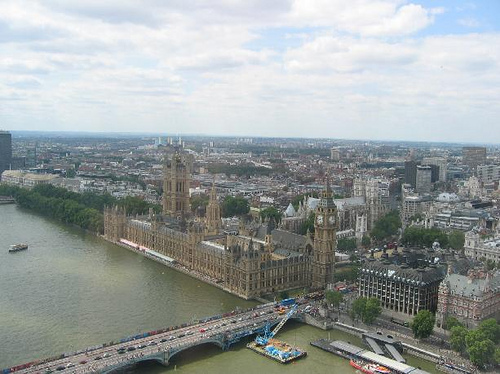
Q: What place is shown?
A: It is a city.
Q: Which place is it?
A: It is a city.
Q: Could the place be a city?
A: Yes, it is a city.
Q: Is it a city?
A: Yes, it is a city.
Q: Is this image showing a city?
A: Yes, it is showing a city.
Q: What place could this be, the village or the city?
A: It is the city.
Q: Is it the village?
A: No, it is the city.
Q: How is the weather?
A: It is cloudy.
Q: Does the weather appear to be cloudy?
A: Yes, it is cloudy.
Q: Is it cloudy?
A: Yes, it is cloudy.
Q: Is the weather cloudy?
A: Yes, it is cloudy.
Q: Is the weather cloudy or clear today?
A: It is cloudy.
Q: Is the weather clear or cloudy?
A: It is cloudy.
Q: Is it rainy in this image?
A: No, it is cloudy.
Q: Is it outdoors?
A: Yes, it is outdoors.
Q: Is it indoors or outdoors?
A: It is outdoors.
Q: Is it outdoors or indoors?
A: It is outdoors.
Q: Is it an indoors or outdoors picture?
A: It is outdoors.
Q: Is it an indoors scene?
A: No, it is outdoors.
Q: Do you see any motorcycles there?
A: No, there are no motorcycles.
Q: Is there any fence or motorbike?
A: No, there are no motorcycles or fences.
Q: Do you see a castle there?
A: Yes, there is a castle.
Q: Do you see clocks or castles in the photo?
A: Yes, there is a castle.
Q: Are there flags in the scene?
A: No, there are no flags.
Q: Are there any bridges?
A: Yes, there is a bridge.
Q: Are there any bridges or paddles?
A: Yes, there is a bridge.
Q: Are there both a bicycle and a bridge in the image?
A: No, there is a bridge but no bicycles.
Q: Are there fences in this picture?
A: No, there are no fences.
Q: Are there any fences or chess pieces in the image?
A: No, there are no fences or chess pieces.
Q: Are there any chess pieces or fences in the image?
A: No, there are no fences or chess pieces.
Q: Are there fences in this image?
A: No, there are no fences.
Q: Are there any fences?
A: No, there are no fences.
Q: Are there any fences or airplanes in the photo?
A: No, there are no fences or airplanes.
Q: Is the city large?
A: Yes, the city is large.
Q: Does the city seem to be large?
A: Yes, the city is large.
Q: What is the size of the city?
A: The city is large.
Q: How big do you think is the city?
A: The city is large.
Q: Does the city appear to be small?
A: No, the city is large.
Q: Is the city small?
A: No, the city is large.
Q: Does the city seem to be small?
A: No, the city is large.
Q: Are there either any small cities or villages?
A: No, there is a city but it is large.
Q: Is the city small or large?
A: The city is large.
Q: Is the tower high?
A: Yes, the tower is high.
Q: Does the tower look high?
A: Yes, the tower is high.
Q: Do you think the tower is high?
A: Yes, the tower is high.